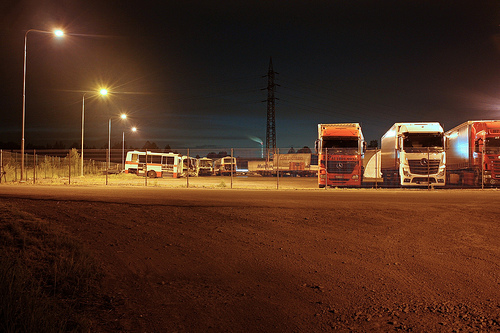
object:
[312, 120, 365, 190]
buses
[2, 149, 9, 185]
pole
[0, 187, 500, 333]
dirt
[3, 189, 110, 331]
patch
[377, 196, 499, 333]
tire tracks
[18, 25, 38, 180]
poles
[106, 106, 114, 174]
poles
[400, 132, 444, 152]
window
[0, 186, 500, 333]
soil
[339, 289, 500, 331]
tracks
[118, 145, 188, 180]
trucks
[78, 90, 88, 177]
pole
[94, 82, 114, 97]
light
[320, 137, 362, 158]
window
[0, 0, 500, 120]
sky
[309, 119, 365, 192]
tractor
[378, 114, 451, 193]
tractor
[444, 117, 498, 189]
tractor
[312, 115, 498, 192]
row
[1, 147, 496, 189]
chainlink fence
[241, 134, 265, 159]
smoke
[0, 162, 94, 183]
weeds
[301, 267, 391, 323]
part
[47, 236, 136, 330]
part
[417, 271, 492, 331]
part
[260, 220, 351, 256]
part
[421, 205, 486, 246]
part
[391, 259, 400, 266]
stones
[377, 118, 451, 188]
truck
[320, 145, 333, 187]
post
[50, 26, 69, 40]
light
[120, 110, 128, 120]
light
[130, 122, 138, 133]
light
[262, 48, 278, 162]
chimney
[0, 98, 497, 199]
lot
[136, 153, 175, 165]
windows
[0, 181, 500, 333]
ground